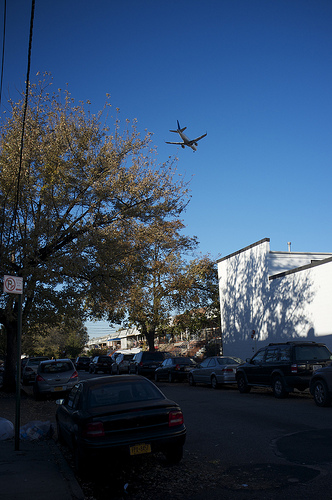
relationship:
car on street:
[55, 373, 186, 468] [42, 363, 331, 499]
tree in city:
[0, 69, 217, 395] [1, 1, 331, 499]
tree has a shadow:
[0, 69, 217, 395] [216, 244, 316, 334]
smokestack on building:
[285, 239, 295, 253] [216, 237, 332, 364]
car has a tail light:
[55, 373, 186, 468] [168, 408, 184, 429]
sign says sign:
[3, 274, 25, 295] [3, 274, 25, 295]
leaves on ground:
[1, 372, 291, 499] [0, 367, 330, 496]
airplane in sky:
[166, 120, 208, 154] [1, 0, 331, 341]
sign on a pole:
[3, 274, 25, 295] [15, 293, 23, 451]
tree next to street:
[0, 69, 217, 395] [42, 363, 331, 499]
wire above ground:
[10, 0, 35, 213] [0, 367, 330, 496]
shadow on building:
[216, 244, 316, 334] [216, 237, 332, 364]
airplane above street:
[166, 120, 208, 154] [42, 363, 331, 499]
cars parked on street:
[20, 339, 331, 469] [42, 363, 331, 499]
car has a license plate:
[55, 373, 186, 468] [128, 442, 153, 456]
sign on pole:
[3, 274, 25, 295] [15, 293, 23, 451]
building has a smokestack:
[216, 237, 332, 364] [285, 239, 295, 253]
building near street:
[216, 237, 332, 364] [42, 363, 331, 499]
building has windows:
[83, 304, 223, 359] [95, 317, 221, 348]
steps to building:
[181, 339, 216, 362] [83, 304, 223, 359]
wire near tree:
[10, 0, 35, 213] [0, 69, 217, 395]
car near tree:
[55, 373, 186, 468] [0, 69, 217, 395]